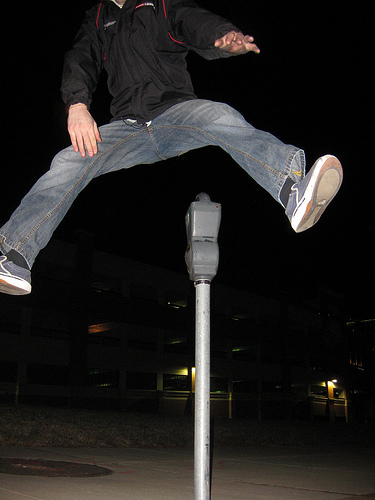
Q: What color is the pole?
A: Gray.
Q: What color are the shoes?
A: Gray.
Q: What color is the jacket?
A: Black.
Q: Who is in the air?
A: Man in black coat.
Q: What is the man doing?
A: Jumping over the parking meter.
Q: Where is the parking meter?
A: Under the man's legs.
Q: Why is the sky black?
A: It is dark.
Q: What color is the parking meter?
A: Gray.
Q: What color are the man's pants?
A: Blue.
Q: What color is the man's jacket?
A: Black.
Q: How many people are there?
A: 1.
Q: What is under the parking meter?
A: Sidewalk.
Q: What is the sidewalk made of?
A: Concrete.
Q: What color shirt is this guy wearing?
A: Black.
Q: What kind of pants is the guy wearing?
A: Jeans.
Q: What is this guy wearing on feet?
A: Sneakers.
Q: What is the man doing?
A: Jumping.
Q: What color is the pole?
A: Gray.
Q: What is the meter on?
A: Parking lot.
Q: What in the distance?
A: Lights.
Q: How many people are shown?
A: One.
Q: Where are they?
A: On the street.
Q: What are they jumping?
A: Parking meter.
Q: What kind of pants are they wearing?
A: Blue Jeans.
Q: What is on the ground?
A: Sidewalk.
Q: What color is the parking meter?
A: Grey.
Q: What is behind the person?
A: Building.